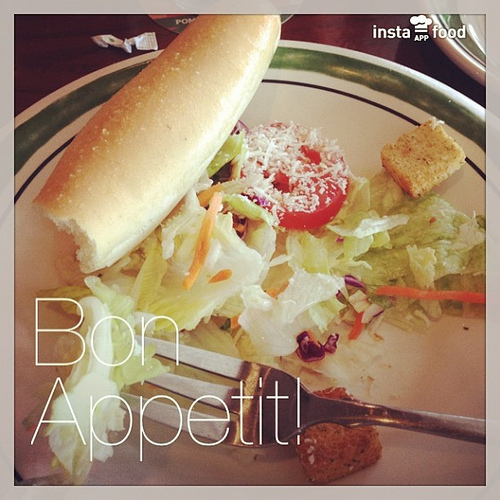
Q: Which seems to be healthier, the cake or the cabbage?
A: The cabbage is healthier than the cake.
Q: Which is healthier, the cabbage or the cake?
A: The cabbage is healthier than the cake.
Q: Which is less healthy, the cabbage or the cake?
A: The cake is less healthy than the cabbage.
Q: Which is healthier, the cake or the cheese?
A: The cheese is healthier than the cake.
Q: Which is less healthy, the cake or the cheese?
A: The cake is less healthy than the cheese.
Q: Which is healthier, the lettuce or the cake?
A: The lettuce is healthier than the cake.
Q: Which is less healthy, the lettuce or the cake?
A: The cake is less healthy than the lettuce.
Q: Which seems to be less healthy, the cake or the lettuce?
A: The cake is less healthy than the lettuce.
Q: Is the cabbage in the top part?
A: No, the cabbage is in the bottom of the image.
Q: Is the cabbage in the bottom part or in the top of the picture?
A: The cabbage is in the bottom of the image.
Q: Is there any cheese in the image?
A: Yes, there is cheese.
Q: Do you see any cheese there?
A: Yes, there is cheese.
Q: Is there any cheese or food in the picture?
A: Yes, there is cheese.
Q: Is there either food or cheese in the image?
A: Yes, there is cheese.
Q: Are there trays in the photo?
A: No, there are no trays.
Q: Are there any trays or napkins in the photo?
A: No, there are no trays or napkins.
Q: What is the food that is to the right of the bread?
A: The food is cheese.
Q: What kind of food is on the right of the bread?
A: The food is cheese.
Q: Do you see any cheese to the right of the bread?
A: Yes, there is cheese to the right of the bread.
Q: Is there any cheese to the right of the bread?
A: Yes, there is cheese to the right of the bread.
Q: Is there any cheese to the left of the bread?
A: No, the cheese is to the right of the bread.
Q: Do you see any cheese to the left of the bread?
A: No, the cheese is to the right of the bread.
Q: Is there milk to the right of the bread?
A: No, there is cheese to the right of the bread.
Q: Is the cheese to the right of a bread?
A: Yes, the cheese is to the right of a bread.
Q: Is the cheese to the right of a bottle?
A: No, the cheese is to the right of a bread.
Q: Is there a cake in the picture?
A: Yes, there is a cake.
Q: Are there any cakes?
A: Yes, there is a cake.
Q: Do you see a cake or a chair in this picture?
A: Yes, there is a cake.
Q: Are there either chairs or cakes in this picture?
A: Yes, there is a cake.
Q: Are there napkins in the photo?
A: No, there are no napkins.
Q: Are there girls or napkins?
A: No, there are no napkins or girls.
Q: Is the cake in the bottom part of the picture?
A: Yes, the cake is in the bottom of the image.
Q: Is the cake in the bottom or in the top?
A: The cake is in the bottom of the image.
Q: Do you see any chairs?
A: Yes, there is a chair.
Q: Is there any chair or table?
A: Yes, there is a chair.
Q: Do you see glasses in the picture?
A: No, there are no glasses.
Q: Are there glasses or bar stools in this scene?
A: No, there are no glasses or bar stools.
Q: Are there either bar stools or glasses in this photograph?
A: No, there are no glasses or bar stools.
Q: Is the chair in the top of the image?
A: Yes, the chair is in the top of the image.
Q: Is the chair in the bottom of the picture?
A: No, the chair is in the top of the image.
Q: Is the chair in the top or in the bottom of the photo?
A: The chair is in the top of the image.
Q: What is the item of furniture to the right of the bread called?
A: The piece of furniture is a chair.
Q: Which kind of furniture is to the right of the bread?
A: The piece of furniture is a chair.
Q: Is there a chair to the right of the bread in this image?
A: Yes, there is a chair to the right of the bread.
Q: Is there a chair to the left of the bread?
A: No, the chair is to the right of the bread.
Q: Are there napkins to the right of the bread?
A: No, there is a chair to the right of the bread.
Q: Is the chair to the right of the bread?
A: Yes, the chair is to the right of the bread.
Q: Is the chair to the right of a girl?
A: No, the chair is to the right of the bread.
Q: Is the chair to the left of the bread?
A: No, the chair is to the right of the bread.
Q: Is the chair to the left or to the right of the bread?
A: The chair is to the right of the bread.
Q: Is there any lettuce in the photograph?
A: Yes, there is lettuce.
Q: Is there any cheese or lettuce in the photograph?
A: Yes, there is lettuce.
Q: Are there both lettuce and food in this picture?
A: Yes, there are both lettuce and food.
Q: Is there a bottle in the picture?
A: No, there are no bottles.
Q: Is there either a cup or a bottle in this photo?
A: No, there are no bottles or cups.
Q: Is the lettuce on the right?
A: Yes, the lettuce is on the right of the image.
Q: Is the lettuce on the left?
A: No, the lettuce is on the right of the image.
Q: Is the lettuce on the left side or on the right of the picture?
A: The lettuce is on the right of the image.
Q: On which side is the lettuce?
A: The lettuce is on the right of the image.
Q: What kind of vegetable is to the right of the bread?
A: The vegetable is lettuce.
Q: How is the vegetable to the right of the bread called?
A: The vegetable is lettuce.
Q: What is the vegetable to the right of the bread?
A: The vegetable is lettuce.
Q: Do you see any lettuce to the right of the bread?
A: Yes, there is lettuce to the right of the bread.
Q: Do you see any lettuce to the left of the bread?
A: No, the lettuce is to the right of the bread.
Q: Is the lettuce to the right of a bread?
A: Yes, the lettuce is to the right of a bread.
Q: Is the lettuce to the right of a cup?
A: No, the lettuce is to the right of a bread.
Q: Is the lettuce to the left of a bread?
A: No, the lettuce is to the right of a bread.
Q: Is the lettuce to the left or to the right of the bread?
A: The lettuce is to the right of the bread.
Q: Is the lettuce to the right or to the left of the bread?
A: The lettuce is to the right of the bread.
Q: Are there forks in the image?
A: Yes, there is a fork.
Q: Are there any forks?
A: Yes, there is a fork.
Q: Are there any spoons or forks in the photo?
A: Yes, there is a fork.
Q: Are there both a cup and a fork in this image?
A: No, there is a fork but no cups.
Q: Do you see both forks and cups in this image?
A: No, there is a fork but no cups.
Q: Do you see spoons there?
A: No, there are no spoons.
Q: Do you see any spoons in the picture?
A: No, there are no spoons.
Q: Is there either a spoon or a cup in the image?
A: No, there are no spoons or cups.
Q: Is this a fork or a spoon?
A: This is a fork.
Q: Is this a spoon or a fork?
A: This is a fork.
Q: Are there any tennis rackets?
A: No, there are no tennis rackets.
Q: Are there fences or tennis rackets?
A: No, there are no tennis rackets or fences.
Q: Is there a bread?
A: Yes, there is a bread.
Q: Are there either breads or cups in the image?
A: Yes, there is a bread.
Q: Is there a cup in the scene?
A: No, there are no cups.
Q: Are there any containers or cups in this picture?
A: No, there are no cups or containers.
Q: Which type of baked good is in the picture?
A: The baked good is a bread.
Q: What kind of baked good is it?
A: The food is a bread.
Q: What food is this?
A: That is a bread.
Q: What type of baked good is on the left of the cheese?
A: The food is a bread.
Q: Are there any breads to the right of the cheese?
A: No, the bread is to the left of the cheese.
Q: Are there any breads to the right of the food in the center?
A: No, the bread is to the left of the cheese.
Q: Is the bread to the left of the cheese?
A: Yes, the bread is to the left of the cheese.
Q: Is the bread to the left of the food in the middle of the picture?
A: Yes, the bread is to the left of the cheese.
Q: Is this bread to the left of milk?
A: No, the bread is to the left of the cheese.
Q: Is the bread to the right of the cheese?
A: No, the bread is to the left of the cheese.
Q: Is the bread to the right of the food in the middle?
A: No, the bread is to the left of the cheese.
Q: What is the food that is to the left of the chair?
A: The food is a bread.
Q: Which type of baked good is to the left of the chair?
A: The food is a bread.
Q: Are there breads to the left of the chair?
A: Yes, there is a bread to the left of the chair.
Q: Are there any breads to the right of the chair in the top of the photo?
A: No, the bread is to the left of the chair.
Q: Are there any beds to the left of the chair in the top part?
A: No, there is a bread to the left of the chair.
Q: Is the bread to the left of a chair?
A: Yes, the bread is to the left of a chair.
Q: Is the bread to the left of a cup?
A: No, the bread is to the left of a chair.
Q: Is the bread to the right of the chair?
A: No, the bread is to the left of the chair.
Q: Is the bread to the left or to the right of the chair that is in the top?
A: The bread is to the left of the chair.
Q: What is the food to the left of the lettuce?
A: The food is a bread.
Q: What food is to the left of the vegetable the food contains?
A: The food is a bread.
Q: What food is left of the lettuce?
A: The food is a bread.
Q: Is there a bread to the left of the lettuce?
A: Yes, there is a bread to the left of the lettuce.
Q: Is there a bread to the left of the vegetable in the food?
A: Yes, there is a bread to the left of the lettuce.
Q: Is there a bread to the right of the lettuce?
A: No, the bread is to the left of the lettuce.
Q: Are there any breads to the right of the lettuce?
A: No, the bread is to the left of the lettuce.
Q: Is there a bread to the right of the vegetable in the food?
A: No, the bread is to the left of the lettuce.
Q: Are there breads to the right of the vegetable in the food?
A: No, the bread is to the left of the lettuce.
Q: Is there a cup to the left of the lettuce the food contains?
A: No, there is a bread to the left of the lettuce.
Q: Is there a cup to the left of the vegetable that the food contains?
A: No, there is a bread to the left of the lettuce.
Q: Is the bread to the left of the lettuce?
A: Yes, the bread is to the left of the lettuce.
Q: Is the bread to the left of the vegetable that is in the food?
A: Yes, the bread is to the left of the lettuce.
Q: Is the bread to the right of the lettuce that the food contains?
A: No, the bread is to the left of the lettuce.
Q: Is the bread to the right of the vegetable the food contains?
A: No, the bread is to the left of the lettuce.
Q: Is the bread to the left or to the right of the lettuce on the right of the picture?
A: The bread is to the left of the lettuce.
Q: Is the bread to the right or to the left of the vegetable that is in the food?
A: The bread is to the left of the lettuce.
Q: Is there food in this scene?
A: Yes, there is food.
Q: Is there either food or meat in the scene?
A: Yes, there is food.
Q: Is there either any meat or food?
A: Yes, there is food.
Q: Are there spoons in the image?
A: No, there are no spoons.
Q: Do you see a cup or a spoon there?
A: No, there are no spoons or cups.